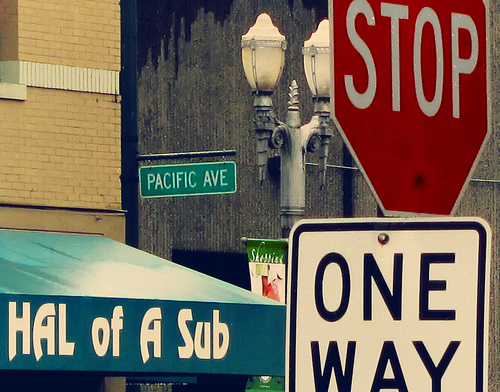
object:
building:
[0, 0, 131, 392]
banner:
[137, 159, 236, 197]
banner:
[0, 299, 283, 370]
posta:
[242, 236, 290, 298]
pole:
[351, 158, 381, 220]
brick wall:
[0, 0, 125, 242]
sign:
[285, 216, 492, 390]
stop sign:
[326, 0, 495, 223]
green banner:
[223, 216, 314, 392]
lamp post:
[252, 74, 331, 238]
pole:
[117, 0, 142, 247]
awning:
[1, 229, 289, 356]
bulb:
[233, 14, 288, 94]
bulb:
[299, 18, 333, 99]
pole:
[275, 74, 310, 247]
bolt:
[376, 233, 390, 248]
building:
[136, 1, 498, 390]